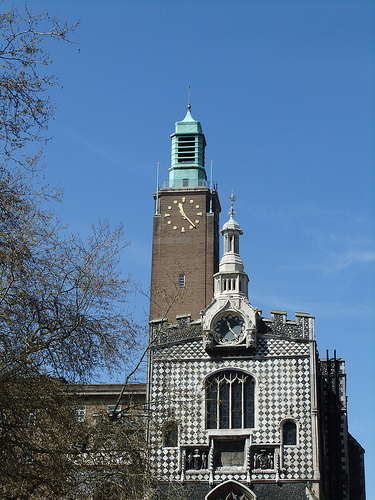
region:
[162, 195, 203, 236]
clock on side of building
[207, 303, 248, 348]
clock centered on building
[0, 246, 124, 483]
several tree branches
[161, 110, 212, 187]
teal top of tower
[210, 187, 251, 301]
white top of tower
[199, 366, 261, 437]
several windows on side of building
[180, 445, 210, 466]
statues on side of building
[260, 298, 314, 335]
rock wall corner of ledge of building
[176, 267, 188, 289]
window in center of brick building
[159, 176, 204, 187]
safety fence rail on ledge of building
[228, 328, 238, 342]
White hand on clock.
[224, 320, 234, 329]
White hand on clock.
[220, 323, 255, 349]
Face of clock is blue.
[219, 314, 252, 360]
Numbers on clock are white.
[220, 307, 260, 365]
Clock is round in shape.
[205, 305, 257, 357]
Clock is near top of building.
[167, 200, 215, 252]
White hands on clock.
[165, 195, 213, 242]
White dots as numbers on clock.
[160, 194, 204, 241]
Clock is on side of brown building.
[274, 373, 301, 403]
Building is gray and white.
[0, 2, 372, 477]
blue of daytime sky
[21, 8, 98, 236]
ends of tree branches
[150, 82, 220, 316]
tall tower with clock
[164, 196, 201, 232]
clock on face of tower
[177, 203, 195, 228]
two white clock hands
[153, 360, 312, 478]
pattern on wall of building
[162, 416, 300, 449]
two arched shaped windows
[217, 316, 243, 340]
clock with blue face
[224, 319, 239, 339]
white hands on blue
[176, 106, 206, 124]
green top of tower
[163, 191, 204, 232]
A large church clock.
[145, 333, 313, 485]
A black and white wall.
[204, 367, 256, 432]
A large church window.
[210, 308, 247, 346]
An outdoor church clock.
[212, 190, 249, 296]
A white church steeple.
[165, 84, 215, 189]
A blue church steeple.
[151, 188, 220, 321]
A brown brick building.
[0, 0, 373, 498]
A bright blue sky.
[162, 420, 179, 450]
A small rounded window.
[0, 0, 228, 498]
An area of tree branches.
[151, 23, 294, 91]
Bright blue skies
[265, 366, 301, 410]
Checkered pattern of the building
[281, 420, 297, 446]
A small window of the building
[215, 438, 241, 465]
Door area of the building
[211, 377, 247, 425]
Large window of the building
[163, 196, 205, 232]
Large clock on a brown building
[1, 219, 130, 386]
Large trees near the buildings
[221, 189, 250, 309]
Design on top of the checkered building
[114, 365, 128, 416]
A branch of the tree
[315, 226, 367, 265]
Thin white cloud in the sky